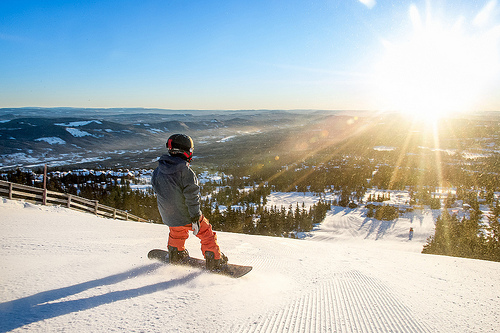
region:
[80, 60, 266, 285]
person on a skateboard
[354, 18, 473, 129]
the sun is bright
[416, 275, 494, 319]
the snow is white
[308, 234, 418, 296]
snow on the hill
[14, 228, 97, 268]
tracks in the snow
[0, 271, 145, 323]
shadow of the boy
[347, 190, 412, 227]
trees at the bottom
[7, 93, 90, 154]
snow on the hill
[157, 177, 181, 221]
the coat is grey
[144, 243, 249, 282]
snowboard on the snow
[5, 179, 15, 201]
wooden board on fence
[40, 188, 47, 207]
wooden board on fence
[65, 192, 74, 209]
wooden board on fence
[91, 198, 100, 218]
wooden board on fence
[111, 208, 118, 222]
wooden board on fence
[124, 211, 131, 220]
wooden board on fence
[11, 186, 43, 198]
wooden board on fence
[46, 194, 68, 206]
wooden board on fence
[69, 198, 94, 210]
wooden board on fence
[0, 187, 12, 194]
wooden board on fence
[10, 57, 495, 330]
A person is up in the mountains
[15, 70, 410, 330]
A person is using a snowboard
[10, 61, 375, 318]
A person is wearing a helmet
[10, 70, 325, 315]
A person is casting a shadow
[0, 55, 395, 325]
A person is getting some exercise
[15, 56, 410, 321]
A person is wearing warm clothes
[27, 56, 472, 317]
A person is out in the sunshine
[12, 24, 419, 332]
A person is enjoying the day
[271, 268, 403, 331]
There straight lines on the snow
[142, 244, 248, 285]
Skateboard rushing on the snow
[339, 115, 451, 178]
Ray of the bright sunlight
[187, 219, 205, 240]
A white with black line glove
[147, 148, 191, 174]
A black hood of the jacket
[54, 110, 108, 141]
Mountains with white snow on the top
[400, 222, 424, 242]
A person waiting down the slope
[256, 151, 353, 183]
A bunch of tall pine trees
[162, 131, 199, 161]
A black with red helmet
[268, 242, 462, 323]
The snow is the color white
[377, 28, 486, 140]
The sun is very bright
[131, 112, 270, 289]
The person is snow boarding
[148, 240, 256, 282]
The snow board is the color black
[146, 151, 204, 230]
The person has on a gray jacket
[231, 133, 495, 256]
The trees are on the ground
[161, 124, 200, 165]
The person is wearing a helmet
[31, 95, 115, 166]
The mountains have ice on them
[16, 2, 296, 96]
The sky is clear and blue